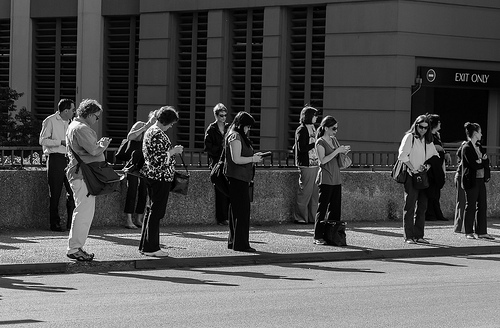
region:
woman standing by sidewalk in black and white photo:
[78, 98, 126, 262]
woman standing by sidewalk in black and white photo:
[143, 105, 181, 254]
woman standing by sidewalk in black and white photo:
[216, 112, 269, 266]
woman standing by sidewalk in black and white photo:
[313, 116, 354, 263]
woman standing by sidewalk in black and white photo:
[398, 115, 451, 252]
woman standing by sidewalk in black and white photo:
[452, 117, 494, 241]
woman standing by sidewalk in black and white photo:
[293, 103, 320, 218]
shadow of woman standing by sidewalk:
[131, 271, 223, 301]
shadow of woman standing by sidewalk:
[291, 253, 380, 279]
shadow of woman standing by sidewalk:
[397, 252, 458, 275]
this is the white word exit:
[449, 63, 474, 87]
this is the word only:
[468, 67, 493, 87]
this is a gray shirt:
[309, 138, 351, 196]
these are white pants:
[44, 170, 105, 261]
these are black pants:
[214, 162, 271, 275]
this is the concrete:
[208, 296, 278, 314]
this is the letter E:
[452, 69, 462, 84]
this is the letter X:
[456, 70, 466, 85]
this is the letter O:
[468, 72, 480, 85]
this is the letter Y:
[481, 71, 494, 88]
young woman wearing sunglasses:
[312, 110, 356, 260]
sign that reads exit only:
[451, 65, 493, 89]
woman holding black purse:
[141, 94, 197, 268]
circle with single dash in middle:
[420, 62, 441, 89]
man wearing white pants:
[56, 86, 121, 273]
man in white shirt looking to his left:
[32, 86, 83, 236]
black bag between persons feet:
[308, 207, 365, 261]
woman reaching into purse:
[391, 101, 441, 252]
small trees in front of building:
[2, 76, 44, 172]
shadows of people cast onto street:
[2, 256, 487, 295]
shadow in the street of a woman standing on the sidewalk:
[85, 271, 238, 298]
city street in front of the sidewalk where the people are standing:
[0, 255, 499, 325]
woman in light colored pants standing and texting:
[66, 96, 107, 259]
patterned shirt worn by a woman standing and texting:
[138, 124, 178, 179]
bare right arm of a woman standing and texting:
[316, 143, 343, 164]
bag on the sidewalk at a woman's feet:
[314, 220, 347, 247]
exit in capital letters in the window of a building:
[451, 67, 472, 85]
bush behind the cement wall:
[1, 84, 45, 169]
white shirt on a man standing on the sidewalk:
[38, 110, 73, 151]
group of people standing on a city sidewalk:
[37, 96, 494, 258]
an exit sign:
[415, 62, 498, 91]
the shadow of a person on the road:
[103, 265, 233, 291]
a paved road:
[8, 251, 497, 324]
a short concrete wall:
[2, 168, 498, 223]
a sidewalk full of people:
[0, 214, 499, 266]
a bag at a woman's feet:
[313, 214, 349, 250]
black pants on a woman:
[221, 173, 256, 255]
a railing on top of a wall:
[0, 144, 498, 167]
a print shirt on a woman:
[141, 125, 181, 179]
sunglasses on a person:
[415, 121, 430, 131]